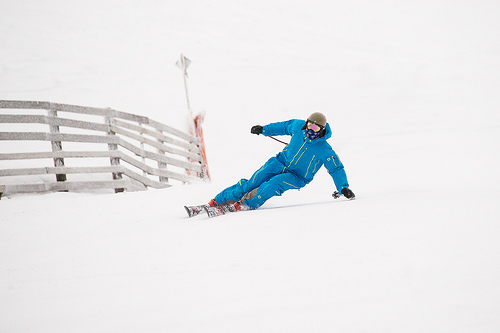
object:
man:
[189, 111, 357, 218]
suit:
[212, 118, 349, 211]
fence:
[0, 98, 210, 201]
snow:
[122, 211, 201, 255]